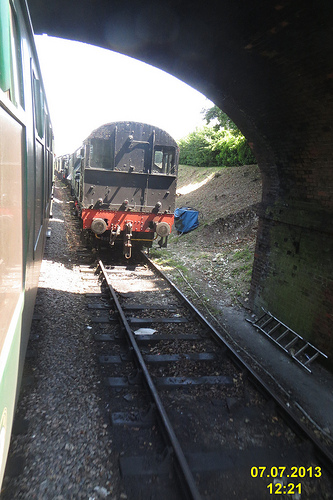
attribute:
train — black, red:
[50, 114, 204, 250]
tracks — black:
[99, 260, 282, 494]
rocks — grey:
[29, 258, 95, 488]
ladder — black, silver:
[257, 302, 320, 378]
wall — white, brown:
[245, 123, 327, 279]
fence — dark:
[1, 53, 54, 285]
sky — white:
[64, 44, 117, 112]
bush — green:
[191, 104, 239, 160]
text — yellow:
[236, 455, 320, 499]